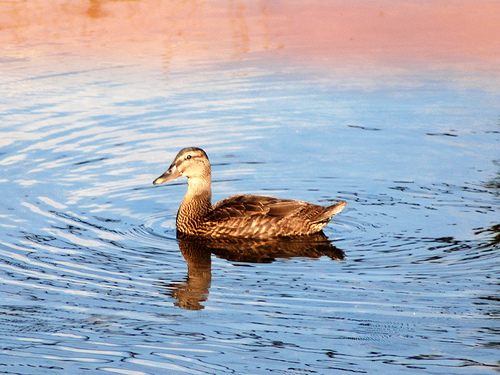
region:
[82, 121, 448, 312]
the duck is brown in color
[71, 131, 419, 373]
the duck is in water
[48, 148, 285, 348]
a reflection is cast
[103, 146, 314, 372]
water is reflecting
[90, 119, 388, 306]
the duck has black eyes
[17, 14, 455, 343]
it is sunny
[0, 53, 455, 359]
it is in a waterbody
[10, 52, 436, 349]
it is a daytime scene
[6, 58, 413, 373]
it is an outdoor scene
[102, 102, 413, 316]
the duck is floating on water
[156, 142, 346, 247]
one duck is seen.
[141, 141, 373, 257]
duck is brown in color.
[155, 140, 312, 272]
duck is swimming.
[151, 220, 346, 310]
reflection is seen in water.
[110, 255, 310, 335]
whorls are formed in water.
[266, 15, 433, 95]
water is blue and pink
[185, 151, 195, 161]
eyes are black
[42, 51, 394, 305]
daytime picture.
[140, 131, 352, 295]
duck is facing the left side of the picture.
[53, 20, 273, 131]
sunlight reflection.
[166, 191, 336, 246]
duck is brown in color.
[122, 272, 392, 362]
whorls are formed in water.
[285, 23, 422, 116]
water is blue and pink in color.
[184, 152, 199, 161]
duck has black eyes.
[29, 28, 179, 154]
sunlight reflection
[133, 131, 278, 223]
duck is facing towards left.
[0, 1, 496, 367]
a pink and blue hue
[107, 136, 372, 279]
a duck in water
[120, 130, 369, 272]
a duck taking a swim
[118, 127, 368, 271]
a duck paddling slowly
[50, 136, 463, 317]
a duck stirring up ripples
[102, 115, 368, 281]
a mallard in the water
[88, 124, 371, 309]
a mallard in a blue pond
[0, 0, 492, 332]
a pink color merges with blue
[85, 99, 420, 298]
the single eye of a duck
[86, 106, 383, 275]
a duck in profile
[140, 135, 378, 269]
Duck on the pond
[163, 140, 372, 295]
The duck is brown and tan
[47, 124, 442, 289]
Ripples in the water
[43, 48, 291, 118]
Purple haze on the water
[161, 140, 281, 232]
Black highlights the ducks head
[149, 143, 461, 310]
Ripples caused by the duck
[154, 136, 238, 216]
The duck has a bill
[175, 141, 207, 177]
The duck has black eyes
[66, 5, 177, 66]
A reflection in the water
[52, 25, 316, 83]
Pink and orange on the water